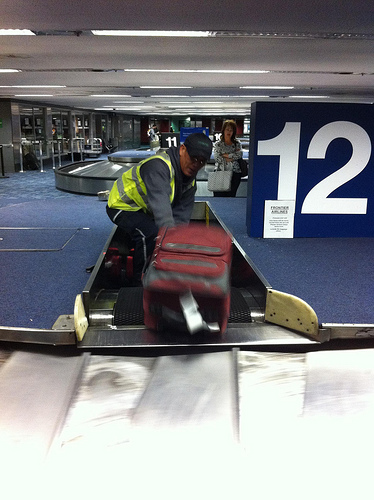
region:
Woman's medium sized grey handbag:
[206, 156, 232, 191]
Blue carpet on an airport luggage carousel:
[1, 193, 372, 330]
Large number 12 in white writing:
[255, 119, 373, 215]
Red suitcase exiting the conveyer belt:
[141, 220, 232, 340]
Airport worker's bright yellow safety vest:
[106, 149, 196, 212]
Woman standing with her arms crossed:
[210, 118, 244, 194]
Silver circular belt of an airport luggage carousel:
[1, 347, 373, 498]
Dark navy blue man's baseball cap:
[183, 130, 212, 165]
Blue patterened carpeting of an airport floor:
[0, 151, 109, 205]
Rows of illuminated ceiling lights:
[0, 0, 331, 114]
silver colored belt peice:
[236, 350, 304, 432]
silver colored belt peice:
[133, 355, 238, 456]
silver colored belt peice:
[58, 353, 152, 462]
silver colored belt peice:
[1, 350, 79, 462]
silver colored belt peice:
[305, 349, 371, 447]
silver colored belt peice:
[99, 162, 123, 181]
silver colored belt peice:
[109, 159, 133, 181]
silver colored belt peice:
[86, 160, 111, 183]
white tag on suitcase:
[178, 293, 203, 330]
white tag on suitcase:
[200, 320, 221, 330]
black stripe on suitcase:
[165, 241, 220, 252]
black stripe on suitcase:
[158, 257, 217, 267]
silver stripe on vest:
[117, 175, 131, 203]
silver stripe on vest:
[129, 163, 147, 205]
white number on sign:
[255, 120, 299, 214]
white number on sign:
[303, 124, 367, 217]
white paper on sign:
[262, 200, 296, 238]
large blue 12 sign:
[247, 102, 372, 235]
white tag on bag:
[180, 294, 200, 331]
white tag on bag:
[201, 320, 222, 334]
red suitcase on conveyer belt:
[90, 218, 262, 344]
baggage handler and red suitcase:
[98, 130, 236, 343]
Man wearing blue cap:
[126, 130, 223, 273]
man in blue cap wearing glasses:
[154, 125, 218, 238]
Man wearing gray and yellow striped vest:
[89, 131, 220, 235]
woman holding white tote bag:
[203, 116, 247, 195]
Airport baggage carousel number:
[237, 90, 373, 241]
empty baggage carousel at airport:
[39, 109, 159, 207]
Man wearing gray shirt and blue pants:
[90, 128, 231, 282]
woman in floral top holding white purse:
[203, 113, 249, 202]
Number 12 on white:
[251, 106, 370, 238]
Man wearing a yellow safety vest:
[104, 130, 204, 217]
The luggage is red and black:
[138, 218, 235, 334]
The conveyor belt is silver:
[0, 320, 372, 476]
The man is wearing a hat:
[172, 129, 211, 178]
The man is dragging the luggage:
[104, 134, 238, 335]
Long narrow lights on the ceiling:
[1, 20, 334, 118]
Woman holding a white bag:
[208, 122, 243, 190]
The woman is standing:
[207, 120, 246, 201]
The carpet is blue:
[4, 161, 371, 321]